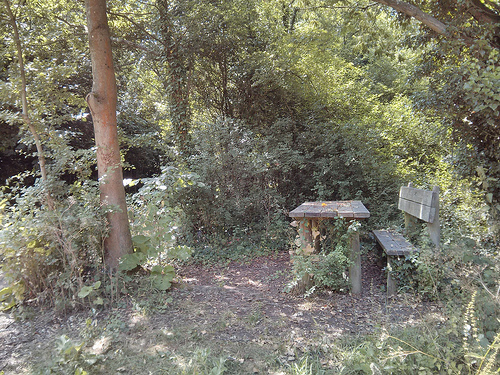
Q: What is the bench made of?
A: Wood.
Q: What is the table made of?
A: Wood.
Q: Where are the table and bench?
A: In the woods.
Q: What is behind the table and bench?
A: Green bushes and trees.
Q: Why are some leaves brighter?
A: The sunlight is streaming through.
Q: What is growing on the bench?
A: Weeds.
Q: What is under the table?
A: Weeds.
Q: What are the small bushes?
A: Shrubs.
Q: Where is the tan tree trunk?
A: On the left.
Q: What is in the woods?
A: Table and bench.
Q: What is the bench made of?
A: Wood.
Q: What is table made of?
A: Wood.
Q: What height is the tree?
A: Tall.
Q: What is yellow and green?
A: Leaves.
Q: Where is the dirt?
A: On ground.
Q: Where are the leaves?
A: On plants.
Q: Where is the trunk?
A: On tree.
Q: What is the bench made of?
A: Wood.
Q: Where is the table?
A: Next to the bench.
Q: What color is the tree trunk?
A: Brown.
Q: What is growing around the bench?
A: Bushes.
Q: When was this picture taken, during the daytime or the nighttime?
A: Daytime.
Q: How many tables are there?
A: One.